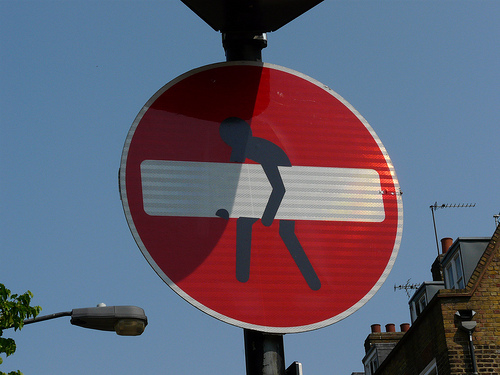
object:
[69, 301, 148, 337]
light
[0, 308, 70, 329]
pole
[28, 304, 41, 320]
leaves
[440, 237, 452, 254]
chimney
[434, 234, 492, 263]
roof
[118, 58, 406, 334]
sign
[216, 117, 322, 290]
human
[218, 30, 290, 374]
pole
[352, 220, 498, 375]
building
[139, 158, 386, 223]
rectangle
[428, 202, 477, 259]
antenna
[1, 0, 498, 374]
sky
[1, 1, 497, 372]
background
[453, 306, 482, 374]
pipe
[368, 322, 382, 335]
chimney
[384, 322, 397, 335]
chimney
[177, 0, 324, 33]
light